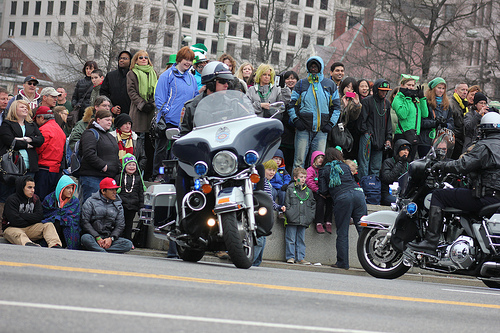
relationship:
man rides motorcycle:
[172, 60, 281, 243] [165, 84, 287, 271]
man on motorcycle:
[172, 50, 266, 242] [165, 84, 287, 271]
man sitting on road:
[81, 175, 130, 257] [28, 234, 156, 321]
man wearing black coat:
[106, 51, 131, 114] [97, 48, 129, 94]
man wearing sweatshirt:
[357, 76, 393, 182] [362, 95, 391, 147]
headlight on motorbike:
[206, 147, 243, 179] [158, 87, 287, 270]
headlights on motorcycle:
[243, 150, 257, 172] [171, 81, 274, 227]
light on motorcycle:
[190, 159, 209, 177] [171, 81, 274, 227]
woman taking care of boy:
[317, 145, 373, 271] [278, 168, 318, 265]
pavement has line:
[2, 242, 499, 332] [0, 297, 399, 333]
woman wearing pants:
[317, 145, 373, 271] [322, 189, 375, 268]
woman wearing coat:
[150, 45, 198, 181] [154, 64, 200, 130]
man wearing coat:
[286, 55, 347, 169] [286, 55, 342, 145]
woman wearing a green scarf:
[126, 49, 158, 181] [130, 60, 155, 102]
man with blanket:
[25, 169, 102, 264] [24, 185, 91, 244]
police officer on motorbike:
[424, 107, 499, 243] [354, 144, 497, 291]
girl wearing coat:
[388, 73, 428, 147] [393, 89, 430, 136]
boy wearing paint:
[264, 157, 326, 263] [294, 176, 301, 186]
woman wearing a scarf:
[150, 45, 198, 183] [165, 50, 255, 98]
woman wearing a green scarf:
[104, 33, 198, 165] [132, 63, 158, 102]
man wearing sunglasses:
[172, 60, 281, 243] [214, 76, 232, 85]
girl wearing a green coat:
[388, 69, 428, 146] [387, 88, 431, 136]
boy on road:
[278, 168, 318, 265] [0, 234, 499, 333]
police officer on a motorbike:
[406, 111, 500, 254] [353, 144, 498, 289]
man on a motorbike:
[172, 60, 281, 243] [158, 87, 287, 271]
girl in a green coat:
[388, 73, 428, 147] [387, 88, 434, 136]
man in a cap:
[77, 175, 137, 255] [96, 175, 122, 190]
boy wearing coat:
[152, 46, 198, 182] [155, 69, 197, 129]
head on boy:
[175, 44, 196, 71] [152, 46, 198, 182]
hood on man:
[304, 53, 323, 79] [286, 53, 346, 169]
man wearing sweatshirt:
[1, 176, 66, 250] [3, 173, 45, 227]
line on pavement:
[2, 260, 499, 309] [2, 242, 499, 332]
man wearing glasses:
[286, 53, 346, 169] [308, 61, 323, 71]